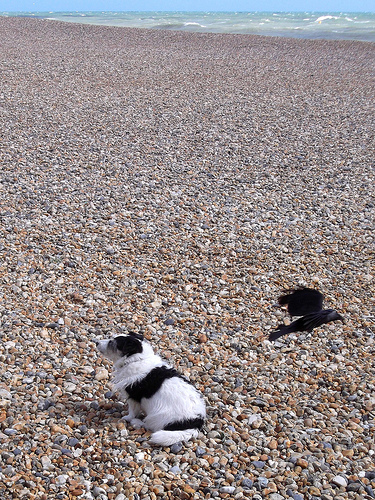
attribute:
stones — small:
[2, 18, 374, 497]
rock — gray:
[238, 476, 255, 489]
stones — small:
[46, 223, 197, 310]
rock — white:
[331, 473, 348, 488]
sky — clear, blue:
[0, 0, 373, 12]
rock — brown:
[234, 412, 249, 421]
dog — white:
[94, 329, 211, 452]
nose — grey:
[93, 337, 101, 348]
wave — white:
[302, 11, 354, 46]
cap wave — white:
[316, 15, 353, 21]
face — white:
[92, 335, 120, 359]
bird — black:
[260, 280, 351, 346]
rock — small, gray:
[252, 460, 265, 470]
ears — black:
[119, 329, 143, 355]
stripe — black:
[126, 365, 175, 402]